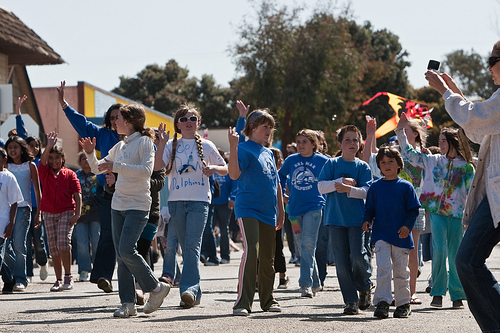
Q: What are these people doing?
A: Walking.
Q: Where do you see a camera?
A: The girl to the far right.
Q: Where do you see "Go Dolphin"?
A: On the girl's white shirt with the sunglasses.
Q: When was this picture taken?
A: During daylight.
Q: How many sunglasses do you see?
A: 2.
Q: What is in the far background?
A: Trees.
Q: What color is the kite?
A: Red, black and yellow.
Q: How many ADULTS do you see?
A: 1.